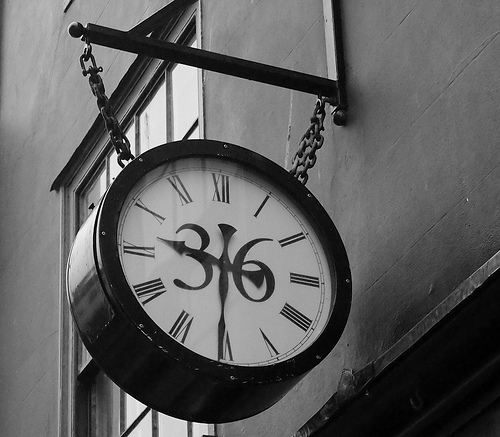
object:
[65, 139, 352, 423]
clock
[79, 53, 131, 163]
chain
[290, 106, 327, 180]
chain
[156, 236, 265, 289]
clock hand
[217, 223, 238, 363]
clock hand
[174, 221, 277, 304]
36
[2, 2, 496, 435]
building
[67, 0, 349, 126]
metal bracket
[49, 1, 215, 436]
window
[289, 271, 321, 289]
roman numerals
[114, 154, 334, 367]
clock face